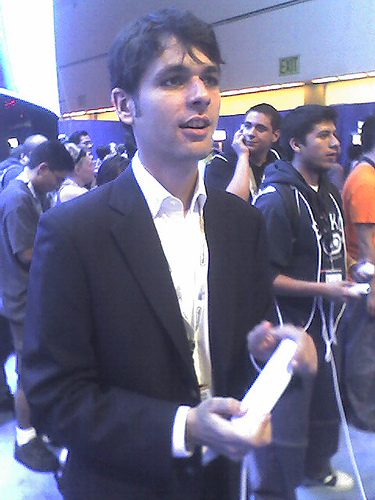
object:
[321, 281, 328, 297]
man wrist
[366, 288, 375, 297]
man wrist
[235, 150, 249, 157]
man wrist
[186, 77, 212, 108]
nose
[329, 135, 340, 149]
nose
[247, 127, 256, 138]
nose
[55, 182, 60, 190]
nose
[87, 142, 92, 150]
nose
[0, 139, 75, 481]
man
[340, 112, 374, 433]
man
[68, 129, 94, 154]
man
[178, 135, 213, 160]
chin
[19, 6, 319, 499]
man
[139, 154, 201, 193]
neck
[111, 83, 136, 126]
ear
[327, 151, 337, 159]
granite top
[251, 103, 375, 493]
man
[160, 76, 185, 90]
eye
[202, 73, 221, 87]
eye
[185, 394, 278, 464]
hand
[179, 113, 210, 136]
mouth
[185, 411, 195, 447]
wrist